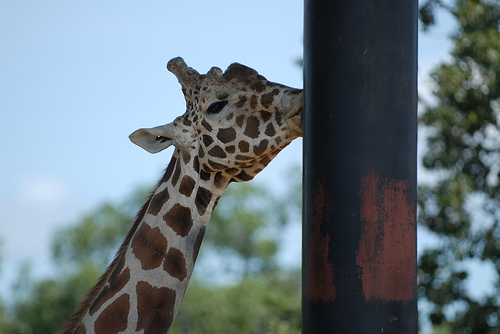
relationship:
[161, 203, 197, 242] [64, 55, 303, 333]
spot on giraffe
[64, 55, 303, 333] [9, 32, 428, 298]
giraffe during day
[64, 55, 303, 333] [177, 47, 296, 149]
giraffe has head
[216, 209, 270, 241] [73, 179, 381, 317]
trees in background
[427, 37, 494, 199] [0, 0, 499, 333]
tree in background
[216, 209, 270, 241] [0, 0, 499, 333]
trees in background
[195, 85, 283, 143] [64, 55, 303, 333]
eyes of giraffe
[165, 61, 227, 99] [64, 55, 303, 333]
horn of giraffe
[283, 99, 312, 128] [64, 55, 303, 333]
lips of giraffe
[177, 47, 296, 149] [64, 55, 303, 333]
head of giraffe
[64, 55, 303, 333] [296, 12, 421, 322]
giraffe kissing pole